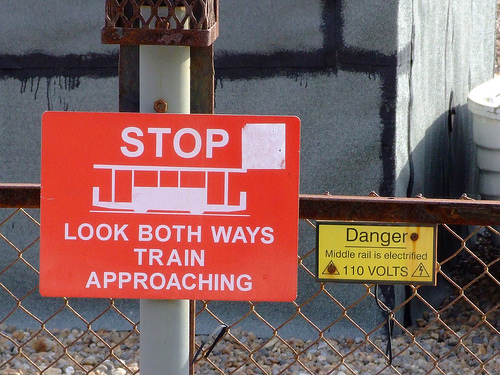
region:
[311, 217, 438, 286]
Yellow sign on the fence.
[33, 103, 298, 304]
Red sign on the post.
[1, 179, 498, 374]
Fence in the forefront.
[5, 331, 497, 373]
Gravel covering the ground.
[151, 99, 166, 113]
Rusted bolt on the pole.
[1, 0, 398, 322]
Black sealer on the concrete structure.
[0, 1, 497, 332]
Concrete structure in the background.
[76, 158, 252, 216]
White train on sign.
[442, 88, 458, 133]
Black circle on side of the building.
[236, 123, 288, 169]
White square on the red sign.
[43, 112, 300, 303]
bright orange stop sign for trains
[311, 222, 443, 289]
danger sign for electric fence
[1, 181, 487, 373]
chain linked fence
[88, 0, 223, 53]
rusted diamond pattern cage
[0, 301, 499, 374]
pebbles strewn on the ground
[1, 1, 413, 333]
black marking on wall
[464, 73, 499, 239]
a white conister with lid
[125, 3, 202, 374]
a white pole holding a traffic sign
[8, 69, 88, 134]
paint dripping down grey wall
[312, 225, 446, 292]
yellow sign is for caution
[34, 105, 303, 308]
the sign is red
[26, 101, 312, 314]
the sign has white writing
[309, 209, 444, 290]
the sign is yellow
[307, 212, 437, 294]
the sign has black writing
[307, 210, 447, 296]
the sign has rust on it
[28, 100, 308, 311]
the sign is on the pole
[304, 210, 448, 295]
the sign is on the fence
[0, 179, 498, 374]
the fence is rusty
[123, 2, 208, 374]
the pole is grey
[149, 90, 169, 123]
the screw is rusty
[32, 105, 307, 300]
a red and white sign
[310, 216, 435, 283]
a yellow danger sign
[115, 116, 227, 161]
sign says stop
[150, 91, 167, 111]
a rusty bolt above the red sign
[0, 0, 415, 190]
black paint on the wall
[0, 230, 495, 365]
stones behind the fence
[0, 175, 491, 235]
the rail is electrified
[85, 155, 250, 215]
a picture of a train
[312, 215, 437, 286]
the sign is black and yellow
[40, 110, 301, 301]
a red and white train warning sign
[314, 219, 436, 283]
a yellow voltage warning sign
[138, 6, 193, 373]
a white sign post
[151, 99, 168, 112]
a bolt on a sign post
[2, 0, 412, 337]
a concrete wall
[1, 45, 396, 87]
black paint on the seam of a concrete wall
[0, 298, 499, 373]
gravel around a building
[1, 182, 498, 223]
a metal rail on the top of a fence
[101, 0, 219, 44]
a metal basket covering the top of a white pole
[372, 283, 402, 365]
a black wire tied on a chain link fence